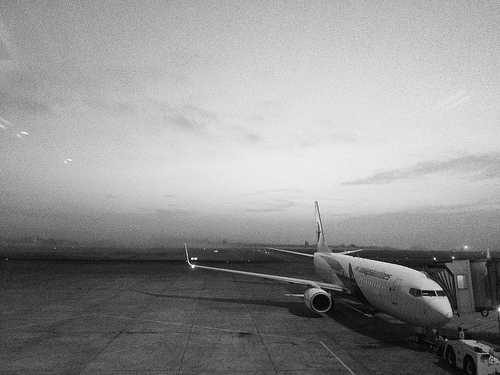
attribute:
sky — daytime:
[0, 32, 500, 282]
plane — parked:
[282, 220, 444, 325]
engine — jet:
[299, 281, 337, 319]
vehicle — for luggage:
[437, 328, 497, 371]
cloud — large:
[306, 178, 423, 199]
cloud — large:
[313, 150, 405, 193]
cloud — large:
[87, 103, 189, 148]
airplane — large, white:
[171, 198, 469, 337]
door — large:
[378, 274, 415, 307]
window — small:
[409, 275, 442, 306]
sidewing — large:
[155, 205, 359, 305]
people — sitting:
[428, 325, 449, 345]